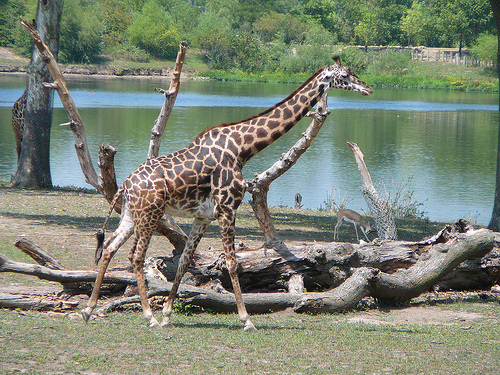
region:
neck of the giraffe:
[233, 94, 316, 143]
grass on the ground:
[188, 333, 231, 362]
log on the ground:
[330, 255, 415, 305]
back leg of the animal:
[55, 246, 121, 312]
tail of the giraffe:
[65, 182, 130, 252]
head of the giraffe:
[310, 51, 375, 97]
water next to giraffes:
[415, 120, 465, 155]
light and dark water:
[410, 140, 460, 185]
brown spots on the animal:
[162, 150, 222, 195]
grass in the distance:
[410, 67, 451, 92]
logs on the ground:
[291, 230, 395, 304]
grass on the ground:
[299, 313, 379, 370]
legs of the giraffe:
[96, 231, 275, 326]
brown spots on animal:
[166, 143, 224, 197]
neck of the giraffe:
[265, 78, 325, 151]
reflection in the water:
[406, 132, 463, 194]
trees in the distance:
[192, 11, 259, 63]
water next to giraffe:
[428, 97, 461, 144]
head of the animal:
[306, 51, 368, 116]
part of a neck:
[252, 109, 287, 148]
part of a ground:
[291, 324, 333, 363]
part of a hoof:
[241, 321, 260, 331]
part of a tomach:
[169, 180, 201, 210]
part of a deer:
[341, 203, 374, 230]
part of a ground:
[362, 321, 393, 348]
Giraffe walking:
[88, 72, 368, 332]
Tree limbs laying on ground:
[38, 231, 448, 311]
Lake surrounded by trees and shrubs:
[31, 52, 471, 209]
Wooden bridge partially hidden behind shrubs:
[221, 35, 476, 71]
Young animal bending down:
[318, 187, 379, 248]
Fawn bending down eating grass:
[325, 198, 370, 246]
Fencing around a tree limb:
[360, 165, 400, 245]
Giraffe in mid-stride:
[61, 197, 256, 333]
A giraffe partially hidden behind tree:
[3, 36, 40, 169]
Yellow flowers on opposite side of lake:
[248, 49, 472, 97]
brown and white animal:
[157, 141, 223, 207]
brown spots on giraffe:
[151, 151, 217, 211]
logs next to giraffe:
[296, 220, 386, 307]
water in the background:
[406, 137, 451, 191]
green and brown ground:
[312, 326, 376, 361]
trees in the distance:
[204, 4, 301, 71]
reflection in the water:
[395, 121, 451, 183]